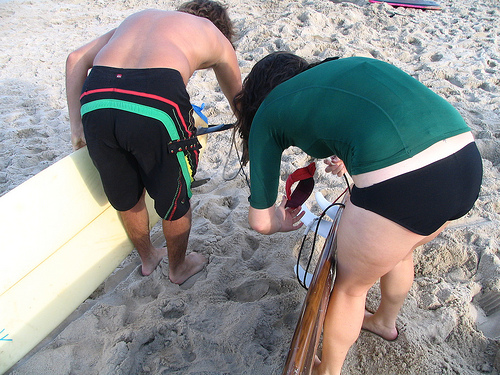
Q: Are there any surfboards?
A: Yes, there is a surfboard.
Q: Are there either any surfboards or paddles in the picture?
A: Yes, there is a surfboard.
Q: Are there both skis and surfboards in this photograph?
A: No, there is a surfboard but no skis.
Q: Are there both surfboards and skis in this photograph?
A: No, there is a surfboard but no skis.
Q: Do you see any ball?
A: No, there are no balls.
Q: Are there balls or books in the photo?
A: No, there are no balls or books.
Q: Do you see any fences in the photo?
A: No, there are no fences.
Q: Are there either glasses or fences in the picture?
A: No, there are no fences or glasses.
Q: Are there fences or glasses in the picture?
A: No, there are no fences or glasses.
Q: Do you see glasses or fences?
A: No, there are no fences or glasses.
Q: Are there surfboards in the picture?
A: Yes, there is a surfboard.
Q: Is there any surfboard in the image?
A: Yes, there is a surfboard.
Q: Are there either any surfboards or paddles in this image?
A: Yes, there is a surfboard.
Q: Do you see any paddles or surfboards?
A: Yes, there is a surfboard.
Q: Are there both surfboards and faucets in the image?
A: No, there is a surfboard but no faucets.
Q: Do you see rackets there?
A: No, there are no rackets.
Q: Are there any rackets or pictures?
A: No, there are no rackets or pictures.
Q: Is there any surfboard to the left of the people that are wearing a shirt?
A: Yes, there is a surfboard to the left of the people.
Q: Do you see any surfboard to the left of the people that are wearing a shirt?
A: Yes, there is a surfboard to the left of the people.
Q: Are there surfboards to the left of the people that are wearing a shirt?
A: Yes, there is a surfboard to the left of the people.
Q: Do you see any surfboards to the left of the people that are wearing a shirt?
A: Yes, there is a surfboard to the left of the people.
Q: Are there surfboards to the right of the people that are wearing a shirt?
A: No, the surfboard is to the left of the people.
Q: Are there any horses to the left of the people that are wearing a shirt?
A: No, there is a surfboard to the left of the people.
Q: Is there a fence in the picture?
A: No, there are no fences.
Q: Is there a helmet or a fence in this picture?
A: No, there are no fences or helmets.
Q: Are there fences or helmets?
A: No, there are no fences or helmets.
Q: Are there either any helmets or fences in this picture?
A: No, there are no fences or helmets.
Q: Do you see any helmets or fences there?
A: No, there are no fences or helmets.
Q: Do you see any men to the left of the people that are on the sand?
A: Yes, there is a man to the left of the people.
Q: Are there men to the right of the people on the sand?
A: No, the man is to the left of the people.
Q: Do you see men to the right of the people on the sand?
A: No, the man is to the left of the people.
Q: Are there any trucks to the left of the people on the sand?
A: No, there is a man to the left of the people.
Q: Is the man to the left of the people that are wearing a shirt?
A: Yes, the man is to the left of the people.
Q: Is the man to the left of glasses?
A: No, the man is to the left of the people.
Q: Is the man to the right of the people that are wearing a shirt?
A: No, the man is to the left of the people.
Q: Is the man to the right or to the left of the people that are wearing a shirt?
A: The man is to the left of the people.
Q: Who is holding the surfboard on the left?
A: The man is holding the surfboard.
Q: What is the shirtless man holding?
A: The man is holding the surfboard.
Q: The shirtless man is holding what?
A: The man is holding the surfboard.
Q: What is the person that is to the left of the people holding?
A: The man is holding the surfboard.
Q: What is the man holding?
A: The man is holding the surfboard.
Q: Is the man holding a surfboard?
A: Yes, the man is holding a surfboard.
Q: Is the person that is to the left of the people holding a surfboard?
A: Yes, the man is holding a surfboard.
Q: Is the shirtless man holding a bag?
A: No, the man is holding a surfboard.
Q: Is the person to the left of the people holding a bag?
A: No, the man is holding a surfboard.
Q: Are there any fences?
A: No, there are no fences.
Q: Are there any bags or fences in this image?
A: No, there are no fences or bags.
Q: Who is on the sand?
A: The people are on the sand.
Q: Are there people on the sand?
A: Yes, there are people on the sand.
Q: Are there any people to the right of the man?
A: Yes, there are people to the right of the man.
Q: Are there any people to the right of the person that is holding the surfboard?
A: Yes, there are people to the right of the man.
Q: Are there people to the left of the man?
A: No, the people are to the right of the man.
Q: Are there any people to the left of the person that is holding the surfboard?
A: No, the people are to the right of the man.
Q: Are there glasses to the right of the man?
A: No, there are people to the right of the man.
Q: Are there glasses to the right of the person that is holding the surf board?
A: No, there are people to the right of the man.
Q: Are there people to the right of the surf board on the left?
A: Yes, there are people to the right of the surfboard.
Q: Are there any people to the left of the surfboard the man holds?
A: No, the people are to the right of the surfboard.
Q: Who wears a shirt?
A: The people wear a shirt.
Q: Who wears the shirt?
A: The people wear a shirt.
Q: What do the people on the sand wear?
A: The people wear a shirt.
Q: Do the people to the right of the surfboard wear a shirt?
A: Yes, the people wear a shirt.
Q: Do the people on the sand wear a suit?
A: No, the people wear a shirt.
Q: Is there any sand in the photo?
A: Yes, there is sand.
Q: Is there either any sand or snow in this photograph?
A: Yes, there is sand.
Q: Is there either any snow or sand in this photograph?
A: Yes, there is sand.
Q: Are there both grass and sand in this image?
A: No, there is sand but no grass.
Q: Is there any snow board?
A: No, there are no snowboards.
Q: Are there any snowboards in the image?
A: No, there are no snowboards.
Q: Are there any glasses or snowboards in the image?
A: No, there are no snowboards or glasses.